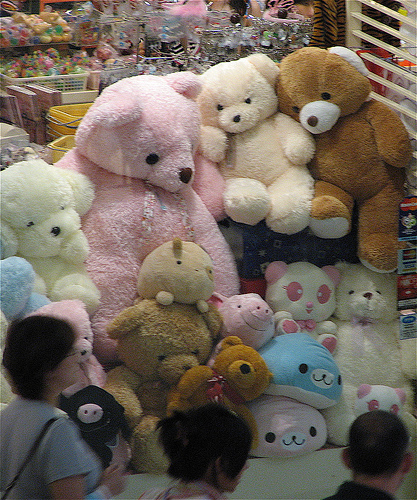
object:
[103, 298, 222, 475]
teddy bear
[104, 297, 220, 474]
brown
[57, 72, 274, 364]
bear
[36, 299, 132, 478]
teddy bear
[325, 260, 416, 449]
teddy bear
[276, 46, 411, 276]
bear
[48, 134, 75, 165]
basket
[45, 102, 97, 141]
basket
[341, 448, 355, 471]
ear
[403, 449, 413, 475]
ear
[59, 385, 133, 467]
pig doll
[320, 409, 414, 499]
individual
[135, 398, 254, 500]
individual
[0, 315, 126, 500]
individual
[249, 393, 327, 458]
toy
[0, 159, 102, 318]
toy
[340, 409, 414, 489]
head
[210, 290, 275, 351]
doll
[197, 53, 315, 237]
bear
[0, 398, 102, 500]
shirt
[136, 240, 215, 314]
stuffed animal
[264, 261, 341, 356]
stuffed animal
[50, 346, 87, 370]
glasses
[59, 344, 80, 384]
face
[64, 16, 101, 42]
item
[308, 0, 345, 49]
item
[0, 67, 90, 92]
item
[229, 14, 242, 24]
item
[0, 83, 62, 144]
books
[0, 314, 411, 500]
people observing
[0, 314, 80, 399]
head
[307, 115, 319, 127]
nose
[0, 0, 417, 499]
store window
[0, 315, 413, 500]
people